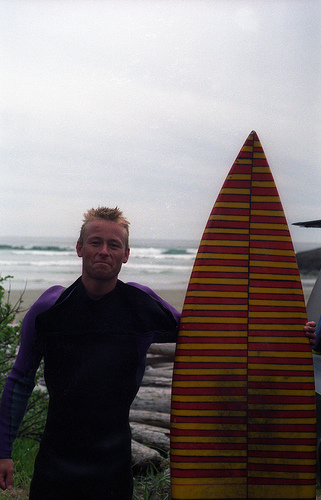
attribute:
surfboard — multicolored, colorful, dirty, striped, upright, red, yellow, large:
[177, 131, 317, 500]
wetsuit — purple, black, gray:
[1, 278, 179, 498]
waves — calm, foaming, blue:
[5, 251, 195, 276]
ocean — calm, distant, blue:
[2, 237, 198, 296]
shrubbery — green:
[1, 272, 50, 461]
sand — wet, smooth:
[3, 278, 195, 314]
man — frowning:
[1, 204, 186, 497]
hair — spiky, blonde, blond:
[77, 205, 133, 226]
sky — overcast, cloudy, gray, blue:
[3, 4, 318, 235]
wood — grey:
[130, 339, 175, 493]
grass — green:
[4, 434, 37, 498]